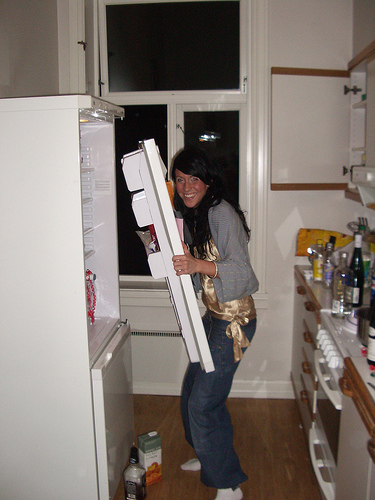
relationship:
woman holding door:
[162, 145, 258, 498] [114, 133, 212, 367]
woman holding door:
[162, 145, 258, 498] [117, 135, 220, 375]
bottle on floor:
[122, 444, 145, 499] [99, 394, 329, 497]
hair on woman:
[188, 158, 213, 179] [161, 147, 225, 226]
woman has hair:
[162, 145, 258, 498] [165, 147, 249, 262]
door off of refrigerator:
[117, 135, 220, 375] [0, 89, 141, 497]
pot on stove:
[347, 300, 372, 351] [269, 274, 372, 445]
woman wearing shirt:
[162, 145, 258, 498] [193, 213, 255, 325]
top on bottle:
[324, 232, 339, 246] [310, 237, 326, 282]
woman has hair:
[162, 145, 258, 498] [158, 143, 261, 260]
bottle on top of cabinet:
[311, 237, 324, 280] [282, 263, 365, 432]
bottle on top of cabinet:
[321, 242, 333, 288] [282, 263, 365, 432]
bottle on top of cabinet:
[332, 251, 348, 318] [282, 263, 365, 432]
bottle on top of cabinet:
[345, 233, 364, 309] [282, 263, 365, 432]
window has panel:
[116, 104, 237, 276] [166, 103, 183, 180]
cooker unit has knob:
[303, 308, 369, 498] [326, 357, 339, 370]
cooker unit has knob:
[303, 308, 369, 498] [324, 351, 334, 364]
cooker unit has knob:
[303, 308, 369, 498] [321, 343, 331, 359]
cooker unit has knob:
[303, 308, 369, 498] [320, 340, 329, 352]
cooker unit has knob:
[303, 308, 369, 498] [315, 328, 323, 343]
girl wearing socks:
[126, 145, 323, 464] [182, 458, 231, 497]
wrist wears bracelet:
[205, 261, 211, 273] [206, 256, 219, 276]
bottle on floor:
[122, 444, 145, 499] [151, 486, 176, 498]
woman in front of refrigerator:
[162, 145, 258, 498] [0, 89, 141, 497]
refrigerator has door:
[0, 94, 122, 497] [87, 374, 140, 407]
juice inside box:
[138, 437, 159, 462] [140, 438, 180, 484]